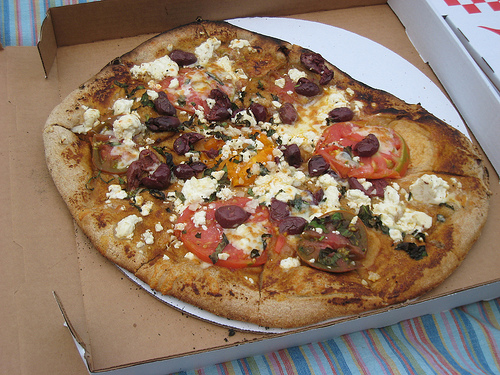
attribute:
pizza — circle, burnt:
[45, 21, 490, 330]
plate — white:
[57, 17, 475, 334]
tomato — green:
[314, 123, 408, 182]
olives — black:
[138, 49, 379, 237]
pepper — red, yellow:
[168, 69, 230, 112]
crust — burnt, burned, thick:
[42, 19, 490, 328]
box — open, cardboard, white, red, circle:
[0, 4, 498, 374]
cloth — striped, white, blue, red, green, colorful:
[1, 1, 500, 373]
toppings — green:
[96, 48, 459, 278]